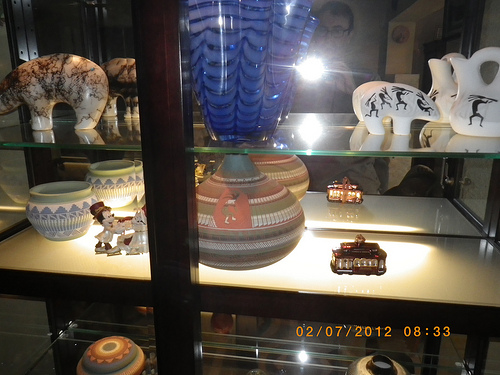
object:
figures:
[0, 51, 500, 170]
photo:
[6, 6, 500, 375]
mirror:
[218, 16, 474, 160]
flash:
[289, 49, 334, 85]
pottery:
[192, 155, 305, 271]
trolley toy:
[327, 233, 390, 279]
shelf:
[0, 178, 499, 328]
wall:
[18, 2, 500, 375]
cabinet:
[1, 0, 500, 375]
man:
[286, 0, 384, 195]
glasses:
[313, 26, 354, 38]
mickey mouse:
[89, 201, 125, 256]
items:
[350, 46, 500, 138]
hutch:
[5, 149, 492, 375]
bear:
[0, 52, 110, 131]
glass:
[179, 0, 309, 148]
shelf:
[187, 100, 495, 160]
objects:
[0, 20, 500, 148]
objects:
[13, 25, 483, 130]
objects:
[24, 155, 389, 292]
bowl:
[22, 180, 96, 242]